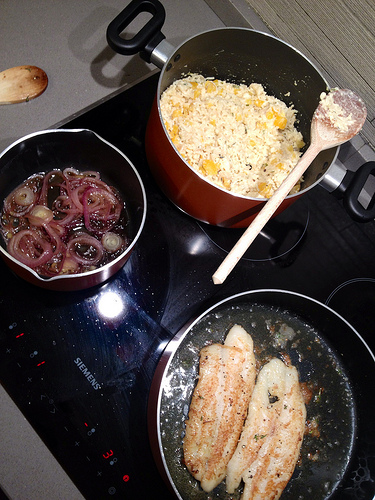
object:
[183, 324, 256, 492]
fish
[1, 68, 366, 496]
stove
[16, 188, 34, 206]
onions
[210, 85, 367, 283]
spoon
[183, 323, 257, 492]
cutlet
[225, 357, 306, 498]
cutlet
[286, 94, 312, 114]
ground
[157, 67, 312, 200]
whatever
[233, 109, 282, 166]
herbs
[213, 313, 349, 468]
oil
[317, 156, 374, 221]
handle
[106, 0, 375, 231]
cook pot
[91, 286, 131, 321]
light reflection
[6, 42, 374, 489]
range top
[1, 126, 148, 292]
pot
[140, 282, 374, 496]
pan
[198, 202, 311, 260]
burner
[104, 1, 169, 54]
handle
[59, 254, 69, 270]
onions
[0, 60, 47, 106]
spoon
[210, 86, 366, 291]
rice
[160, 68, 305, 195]
food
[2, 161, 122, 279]
food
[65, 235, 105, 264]
onions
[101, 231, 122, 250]
onions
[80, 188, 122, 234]
onions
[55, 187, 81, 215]
onions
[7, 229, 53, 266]
onions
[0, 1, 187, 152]
counter top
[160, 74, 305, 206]
rice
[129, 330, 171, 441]
handles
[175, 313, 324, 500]
food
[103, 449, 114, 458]
number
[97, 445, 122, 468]
3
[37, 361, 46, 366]
number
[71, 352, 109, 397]
siemens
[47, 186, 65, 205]
oil